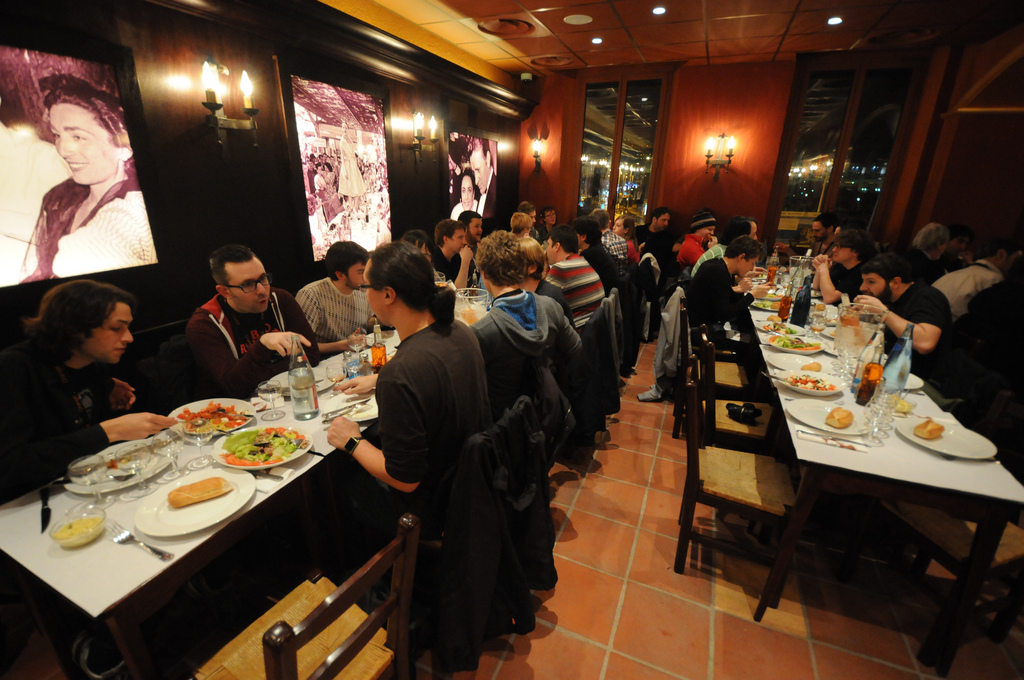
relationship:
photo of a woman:
[14, 52, 164, 286] [26, 72, 147, 261]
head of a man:
[206, 245, 274, 319] [164, 243, 348, 410]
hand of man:
[256, 325, 317, 375] [183, 242, 311, 394]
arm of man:
[183, 309, 296, 403] [186, 238, 323, 398]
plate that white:
[131, 463, 257, 540] [181, 499, 234, 627]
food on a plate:
[240, 438, 310, 464] [195, 416, 325, 468]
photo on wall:
[0, 45, 162, 288] [3, 5, 539, 539]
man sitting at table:
[172, 237, 320, 404] [1, 287, 499, 644]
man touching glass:
[172, 237, 320, 404] [285, 348, 314, 420]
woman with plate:
[4, 290, 169, 453] [81, 413, 203, 474]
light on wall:
[202, 62, 229, 119] [1, 6, 529, 406]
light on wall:
[233, 65, 264, 115] [1, 6, 529, 406]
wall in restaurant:
[1, 6, 529, 406] [1, 4, 1023, 676]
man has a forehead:
[183, 243, 320, 405] [229, 262, 264, 280]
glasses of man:
[219, 266, 269, 297] [186, 238, 323, 398]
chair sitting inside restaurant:
[186, 506, 424, 677] [1, 4, 1023, 676]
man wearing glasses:
[183, 243, 320, 405] [215, 266, 267, 295]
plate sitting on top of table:
[130, 463, 256, 543] [1, 297, 496, 676]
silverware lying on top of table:
[102, 521, 174, 563] [1, 297, 496, 676]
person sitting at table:
[1, 275, 185, 504] [1, 297, 496, 676]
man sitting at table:
[183, 243, 320, 405] [1, 297, 496, 676]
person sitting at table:
[288, 240, 373, 357] [1, 297, 496, 676]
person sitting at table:
[325, 240, 498, 543] [1, 297, 496, 676]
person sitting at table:
[467, 225, 589, 401] [1, 297, 496, 676]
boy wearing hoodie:
[463, 225, 585, 420] [469, 290, 586, 433]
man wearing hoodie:
[183, 243, 320, 405] [176, 282, 319, 397]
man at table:
[841, 260, 958, 394] [733, 258, 1021, 580]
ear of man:
[215, 278, 226, 294] [178, 254, 297, 380]